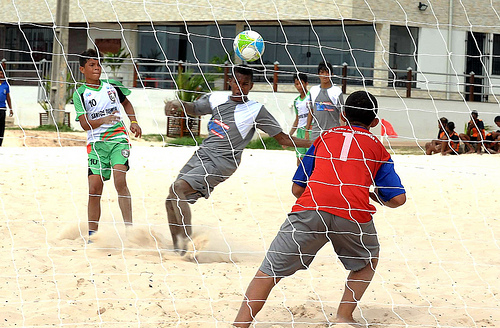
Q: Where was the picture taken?
A: On the beach.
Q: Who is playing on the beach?
A: Children.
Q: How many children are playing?
A: Five.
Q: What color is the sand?
A: Tan.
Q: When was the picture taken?
A: During the day.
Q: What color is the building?
A: White.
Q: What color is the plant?
A: Green.